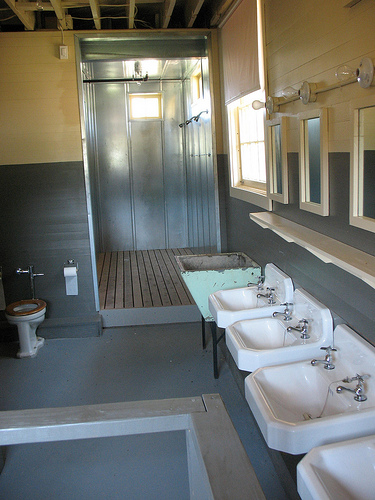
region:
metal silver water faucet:
[330, 369, 369, 400]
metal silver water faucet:
[309, 341, 339, 370]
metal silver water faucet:
[286, 319, 310, 339]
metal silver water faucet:
[269, 301, 294, 322]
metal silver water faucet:
[256, 287, 276, 303]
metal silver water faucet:
[245, 277, 263, 293]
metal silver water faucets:
[245, 272, 276, 304]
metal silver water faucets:
[269, 295, 309, 342]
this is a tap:
[304, 337, 337, 372]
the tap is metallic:
[336, 376, 353, 392]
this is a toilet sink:
[8, 289, 46, 346]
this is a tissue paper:
[57, 262, 83, 305]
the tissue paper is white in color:
[61, 272, 75, 296]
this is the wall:
[10, 57, 52, 141]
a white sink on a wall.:
[207, 265, 294, 328]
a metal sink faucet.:
[271, 294, 302, 324]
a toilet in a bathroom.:
[4, 287, 55, 359]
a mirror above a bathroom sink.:
[293, 102, 339, 217]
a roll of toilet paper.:
[61, 260, 80, 300]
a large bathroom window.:
[218, 86, 272, 204]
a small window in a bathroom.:
[122, 89, 164, 122]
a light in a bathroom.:
[246, 93, 274, 113]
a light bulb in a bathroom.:
[324, 60, 371, 91]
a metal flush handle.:
[8, 256, 55, 289]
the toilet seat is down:
[6, 297, 44, 317]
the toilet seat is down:
[9, 295, 43, 323]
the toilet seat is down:
[5, 294, 45, 324]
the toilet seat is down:
[7, 295, 46, 330]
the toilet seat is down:
[5, 292, 46, 318]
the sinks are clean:
[212, 286, 362, 488]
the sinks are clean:
[220, 295, 349, 484]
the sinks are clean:
[208, 284, 299, 417]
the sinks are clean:
[205, 294, 326, 422]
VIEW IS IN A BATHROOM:
[8, 204, 363, 467]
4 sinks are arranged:
[231, 272, 372, 462]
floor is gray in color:
[100, 340, 203, 398]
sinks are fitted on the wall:
[251, 272, 373, 454]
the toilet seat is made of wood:
[6, 288, 38, 319]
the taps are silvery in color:
[274, 302, 323, 351]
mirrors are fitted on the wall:
[286, 109, 373, 187]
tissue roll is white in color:
[61, 266, 86, 300]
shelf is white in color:
[249, 211, 359, 288]